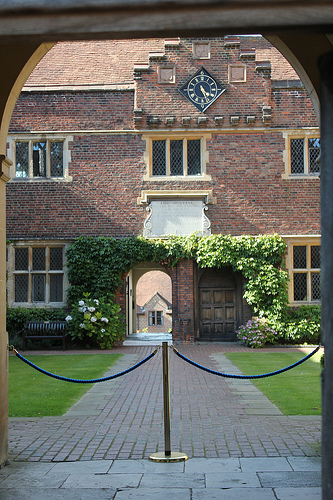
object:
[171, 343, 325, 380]
rope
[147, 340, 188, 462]
post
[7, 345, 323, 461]
sidewalk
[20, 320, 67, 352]
bench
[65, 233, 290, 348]
foliage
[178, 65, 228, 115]
clock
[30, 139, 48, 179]
window pane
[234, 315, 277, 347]
bush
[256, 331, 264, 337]
flower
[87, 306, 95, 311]
flower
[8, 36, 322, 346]
wall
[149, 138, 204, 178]
window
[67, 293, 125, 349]
bush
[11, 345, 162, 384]
rope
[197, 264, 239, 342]
door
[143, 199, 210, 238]
plaque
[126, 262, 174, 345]
walkway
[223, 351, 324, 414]
grass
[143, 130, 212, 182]
frame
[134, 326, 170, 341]
path